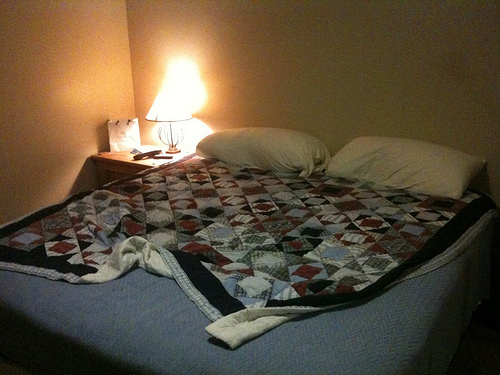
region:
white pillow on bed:
[331, 129, 478, 207]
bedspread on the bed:
[133, 180, 320, 265]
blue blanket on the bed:
[280, 335, 406, 370]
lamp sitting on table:
[149, 61, 196, 158]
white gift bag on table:
[106, 100, 141, 155]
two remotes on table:
[132, 149, 174, 162]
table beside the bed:
[90, 147, 144, 179]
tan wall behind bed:
[261, 55, 437, 107]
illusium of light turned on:
[168, 55, 215, 99]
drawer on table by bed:
[102, 170, 125, 180]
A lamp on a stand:
[155, 73, 196, 155]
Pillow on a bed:
[328, 127, 492, 197]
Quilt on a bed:
[179, 186, 419, 344]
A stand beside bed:
[85, 143, 189, 180]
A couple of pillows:
[190, 116, 462, 195]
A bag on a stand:
[100, 109, 149, 157]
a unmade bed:
[42, 147, 433, 349]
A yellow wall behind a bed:
[240, 15, 482, 109]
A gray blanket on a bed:
[48, 295, 172, 355]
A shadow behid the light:
[169, 59, 238, 104]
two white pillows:
[210, 120, 485, 215]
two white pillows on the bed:
[142, 122, 478, 373]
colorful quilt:
[163, 160, 428, 328]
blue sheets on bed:
[27, 210, 374, 374]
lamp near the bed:
[132, 67, 219, 147]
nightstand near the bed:
[78, 66, 477, 313]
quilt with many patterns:
[155, 127, 473, 371]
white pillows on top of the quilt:
[193, 115, 498, 221]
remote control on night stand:
[112, 128, 203, 188]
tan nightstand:
[89, 114, 199, 203]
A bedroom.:
[9, 12, 498, 374]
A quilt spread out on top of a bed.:
[1, 145, 495, 345]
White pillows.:
[201, 120, 482, 201]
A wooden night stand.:
[86, 134, 197, 196]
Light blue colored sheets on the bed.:
[3, 251, 498, 373]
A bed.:
[0, 125, 480, 373]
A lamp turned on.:
[141, 78, 202, 163]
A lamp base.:
[154, 125, 189, 154]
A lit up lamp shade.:
[140, 77, 207, 122]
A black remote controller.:
[127, 147, 164, 160]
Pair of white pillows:
[210, 125, 497, 218]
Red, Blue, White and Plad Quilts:
[18, 184, 468, 297]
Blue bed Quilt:
[47, 288, 437, 373]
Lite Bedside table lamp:
[154, 86, 188, 155]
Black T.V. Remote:
[133, 149, 175, 160]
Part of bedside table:
[96, 152, 169, 171]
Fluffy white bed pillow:
[349, 122, 479, 199]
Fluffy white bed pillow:
[215, 118, 319, 168]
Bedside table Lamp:
[146, 81, 198, 153]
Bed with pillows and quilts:
[33, 116, 492, 373]